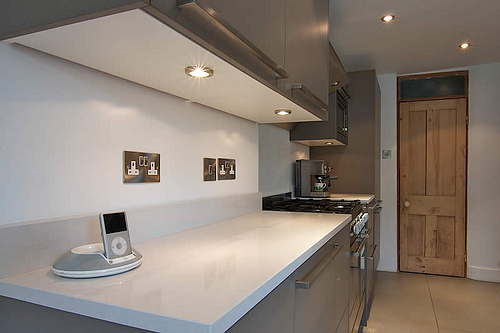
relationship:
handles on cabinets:
[153, 1, 332, 119] [2, 2, 329, 122]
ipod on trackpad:
[99, 210, 136, 261] [51, 241, 146, 277]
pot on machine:
[310, 174, 330, 193] [296, 152, 335, 199]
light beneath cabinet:
[184, 66, 212, 78] [3, 9, 333, 125]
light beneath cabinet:
[274, 109, 292, 115] [290, 85, 347, 146]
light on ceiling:
[380, 13, 394, 22] [326, 0, 498, 75]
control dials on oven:
[352, 210, 369, 236] [350, 200, 369, 332]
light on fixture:
[177, 57, 217, 91] [190, 67, 211, 76]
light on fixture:
[265, 100, 301, 134] [190, 67, 211, 76]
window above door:
[396, 71, 463, 96] [398, 103, 465, 277]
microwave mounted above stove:
[275, 102, 355, 170] [256, 176, 384, 323]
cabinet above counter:
[3, 9, 333, 125] [1, 210, 355, 332]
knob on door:
[402, 200, 414, 214] [393, 100, 468, 279]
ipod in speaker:
[99, 210, 131, 259] [46, 239, 145, 277]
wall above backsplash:
[16, 41, 281, 215] [9, 189, 275, 281]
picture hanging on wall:
[122, 150, 160, 182] [1, 43, 315, 226]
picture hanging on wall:
[190, 151, 220, 184] [1, 43, 315, 226]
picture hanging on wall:
[215, 154, 245, 182] [1, 43, 315, 226]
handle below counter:
[294, 240, 346, 290] [1, 210, 355, 332]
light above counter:
[177, 57, 217, 91] [150, 210, 286, 285]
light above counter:
[274, 109, 292, 115] [150, 210, 286, 285]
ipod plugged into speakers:
[99, 210, 131, 259] [52, 240, 139, 277]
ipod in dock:
[99, 210, 131, 259] [54, 239, 126, 275]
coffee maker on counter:
[293, 158, 338, 198] [287, 181, 379, 206]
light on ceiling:
[380, 12, 394, 22] [326, 0, 498, 75]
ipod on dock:
[99, 210, 131, 259] [48, 240, 144, 278]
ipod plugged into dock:
[99, 210, 131, 259] [50, 236, 146, 284]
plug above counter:
[114, 143, 185, 186] [12, 198, 358, 331]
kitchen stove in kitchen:
[262, 197, 360, 213] [4, 0, 499, 328]